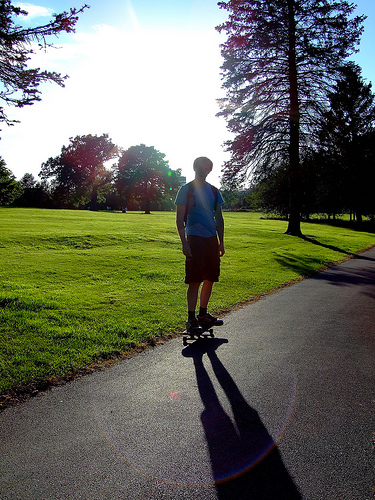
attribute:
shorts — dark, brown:
[175, 233, 221, 286]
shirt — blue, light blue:
[171, 180, 226, 240]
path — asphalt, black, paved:
[6, 241, 374, 499]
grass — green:
[2, 206, 375, 397]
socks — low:
[177, 306, 212, 318]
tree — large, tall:
[216, 2, 364, 238]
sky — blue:
[7, 6, 375, 201]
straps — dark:
[183, 185, 193, 214]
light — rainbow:
[83, 348, 301, 485]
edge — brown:
[7, 248, 375, 401]